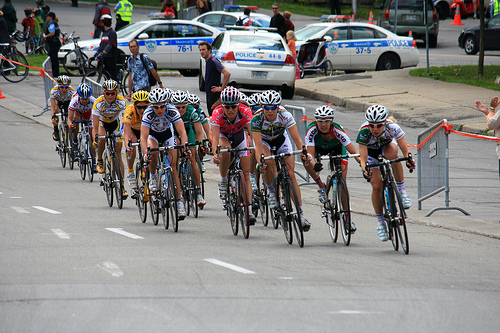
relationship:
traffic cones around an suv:
[364, 10, 467, 43] [374, 0, 441, 47]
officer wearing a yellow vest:
[110, 1, 138, 27] [116, 0, 134, 21]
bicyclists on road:
[44, 71, 421, 254] [0, 96, 417, 330]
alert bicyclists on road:
[49, 75, 416, 255] [1, 90, 476, 330]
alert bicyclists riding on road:
[38, 68, 427, 298] [1, 187, 477, 328]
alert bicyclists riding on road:
[49, 75, 416, 255] [3, 160, 425, 330]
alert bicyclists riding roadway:
[49, 75, 416, 255] [1, 111, 483, 329]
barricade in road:
[417, 119, 470, 217] [0, 76, 500, 333]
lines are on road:
[25, 201, 265, 284] [2, 50, 498, 330]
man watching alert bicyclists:
[192, 45, 230, 106] [49, 75, 416, 255]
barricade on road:
[399, 113, 479, 223] [0, 76, 500, 333]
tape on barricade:
[413, 117, 466, 152] [389, 116, 472, 232]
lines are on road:
[0, 193, 383, 333] [2, 50, 498, 330]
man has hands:
[189, 36, 231, 116] [209, 76, 229, 97]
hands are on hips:
[209, 76, 229, 97] [194, 72, 223, 95]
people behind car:
[234, 0, 299, 70] [194, 3, 301, 55]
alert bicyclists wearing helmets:
[49, 75, 416, 255] [48, 70, 388, 125]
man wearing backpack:
[113, 40, 163, 91] [138, 52, 163, 82]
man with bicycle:
[76, 4, 126, 73] [63, 49, 126, 75]